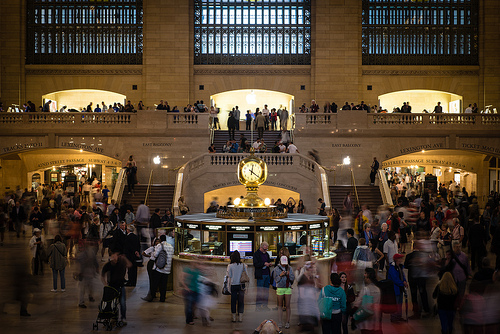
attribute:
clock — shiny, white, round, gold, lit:
[239, 158, 263, 182]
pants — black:
[231, 283, 246, 312]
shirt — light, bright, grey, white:
[384, 238, 399, 260]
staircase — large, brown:
[323, 168, 386, 214]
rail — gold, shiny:
[349, 167, 361, 205]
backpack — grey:
[157, 243, 169, 267]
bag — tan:
[239, 264, 251, 284]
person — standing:
[369, 155, 382, 186]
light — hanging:
[151, 153, 163, 164]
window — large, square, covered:
[28, 2, 143, 65]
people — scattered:
[0, 95, 499, 333]